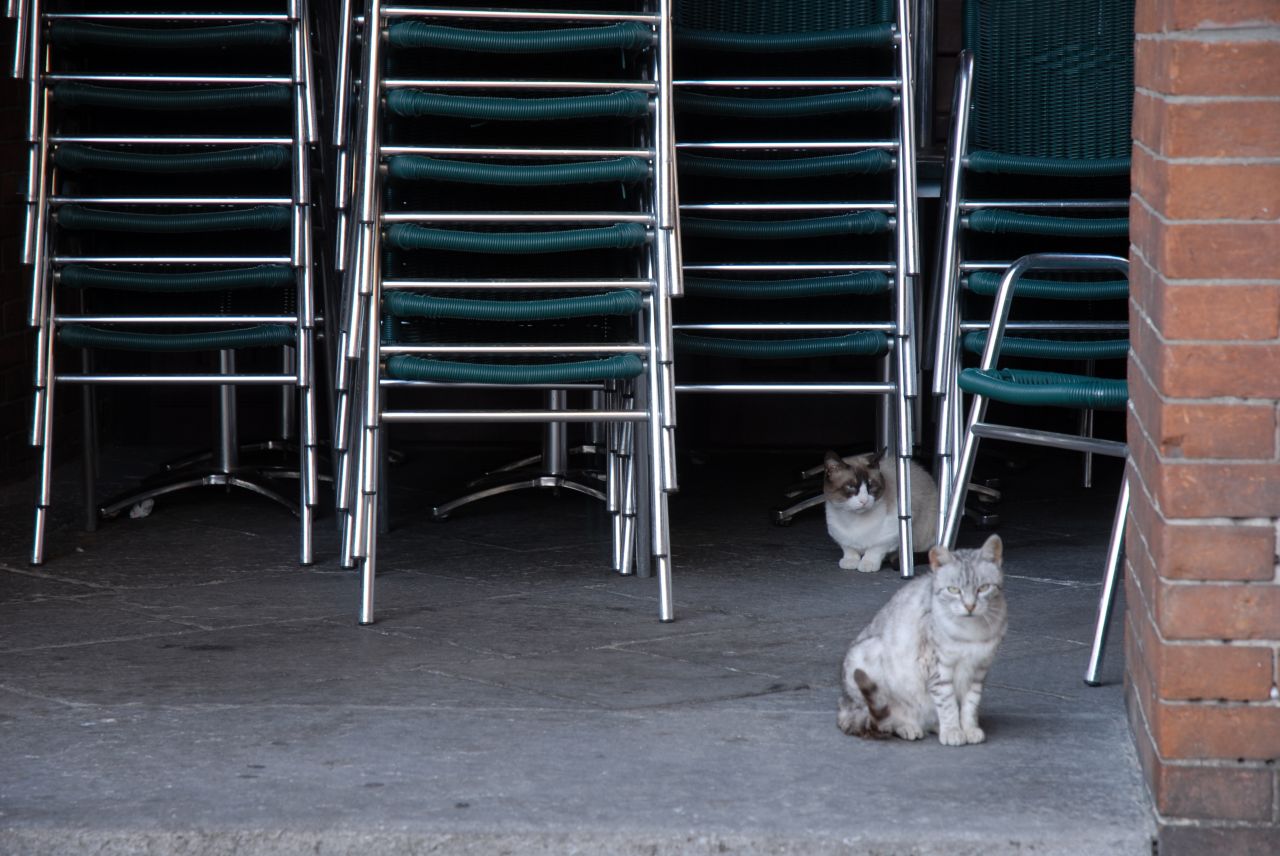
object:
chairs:
[18, 268, 337, 570]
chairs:
[333, 226, 692, 566]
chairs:
[648, 290, 905, 580]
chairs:
[926, 264, 1133, 540]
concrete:
[559, 587, 1016, 749]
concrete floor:
[179, 633, 693, 813]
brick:
[1131, 92, 1278, 162]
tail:
[834, 670, 893, 739]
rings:
[856, 681, 881, 694]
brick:
[1124, 247, 1278, 340]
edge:
[6, 773, 1158, 847]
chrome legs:
[638, 392, 685, 628]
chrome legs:
[331, 391, 391, 635]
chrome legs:
[12, 364, 64, 577]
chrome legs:
[886, 363, 934, 583]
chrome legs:
[937, 350, 984, 587]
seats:
[374, 11, 656, 54]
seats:
[672, 247, 914, 303]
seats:
[957, 347, 1134, 410]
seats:
[39, 296, 308, 363]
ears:
[925, 544, 962, 571]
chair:
[926, 248, 1127, 698]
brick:
[1121, 355, 1276, 461]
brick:
[1123, 141, 1278, 224]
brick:
[1123, 296, 1278, 401]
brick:
[1123, 197, 1277, 282]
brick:
[1126, 34, 1277, 101]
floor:
[16, 407, 1158, 847]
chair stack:
[937, 0, 1129, 565]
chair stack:
[20, 3, 329, 589]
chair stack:
[339, 0, 681, 637]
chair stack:
[662, 0, 924, 577]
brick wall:
[1122, 9, 1274, 820]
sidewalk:
[14, 428, 1154, 813]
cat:
[833, 533, 1012, 748]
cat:
[819, 446, 951, 574]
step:
[4, 760, 1201, 851]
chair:
[339, 316, 703, 628]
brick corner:
[1077, 58, 1250, 795]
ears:
[817, 453, 851, 477]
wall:
[1091, 14, 1276, 812]